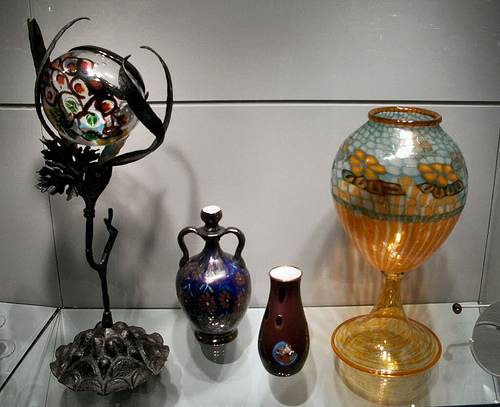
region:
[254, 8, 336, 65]
part of a wall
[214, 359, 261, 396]
part of a surface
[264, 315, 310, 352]
part of a vase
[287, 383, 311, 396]
part of a shade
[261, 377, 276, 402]
edge of a shade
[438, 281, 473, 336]
part of a bolt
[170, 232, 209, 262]
part of a handle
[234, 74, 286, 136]
part of a line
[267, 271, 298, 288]
top of the vase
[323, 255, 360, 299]
part of a shade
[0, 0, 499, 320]
the wall is white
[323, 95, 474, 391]
the vase is orange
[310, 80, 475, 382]
the vase is glass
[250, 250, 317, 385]
the small vase is maroon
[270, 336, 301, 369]
the small vase has a small circle painted on it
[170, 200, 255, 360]
the small blue vase has handles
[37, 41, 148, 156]
the glass ball is painted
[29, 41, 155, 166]
the glass ball is on a metal stand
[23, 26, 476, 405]
several pieces of glass art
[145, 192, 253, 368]
the small blue vase has red flowers painted on it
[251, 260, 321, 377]
brown artisan pottery vase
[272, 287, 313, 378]
decorative holes in a pottery vase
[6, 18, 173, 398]
a work of art in metal and glass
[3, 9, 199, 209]
glass globe on the top of a work of art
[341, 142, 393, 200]
yellow glass flower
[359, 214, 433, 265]
stripes of yellow and clear glass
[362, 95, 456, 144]
opening at the top of an item made of glass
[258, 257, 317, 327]
vase with brown exterior and white interior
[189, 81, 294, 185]
light grey colored wall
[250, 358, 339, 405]
shadow of a vase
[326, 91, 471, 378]
Glass vase on a table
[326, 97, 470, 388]
Vase with flower decorations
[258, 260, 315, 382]
Small porcelain vase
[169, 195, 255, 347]
Porcelain blue carafe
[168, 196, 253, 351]
Porcelain blue carafe with two handles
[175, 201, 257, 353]
Oval porcelain carafe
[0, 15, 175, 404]
Metal support for ornament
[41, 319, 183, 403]
Base of metal support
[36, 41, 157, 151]
Transparent round decoration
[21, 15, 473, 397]
Ornaments on a table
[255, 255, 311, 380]
Decorated vase of ceramic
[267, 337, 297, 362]
Decoration on ceramic vase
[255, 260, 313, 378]
Ceramic vase with white interior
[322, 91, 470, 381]
Glass vase with flowers decoration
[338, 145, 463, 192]
Flower decoration on a vase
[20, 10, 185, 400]
Metal holder for a decoration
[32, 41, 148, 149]
Round transparent decoration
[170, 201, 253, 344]
Carafe with handles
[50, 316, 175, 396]
Base of holder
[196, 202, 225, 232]
lid of carafe